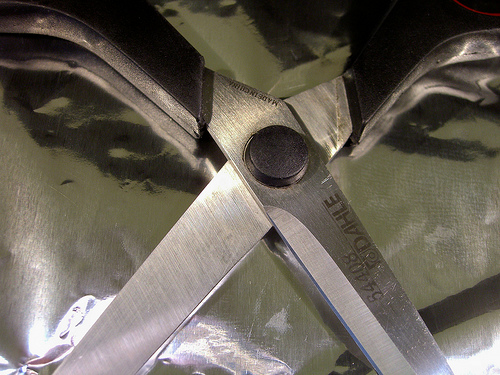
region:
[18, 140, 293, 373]
this is a blade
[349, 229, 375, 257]
this is the letter d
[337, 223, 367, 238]
this is the letter a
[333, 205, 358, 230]
this is the letter h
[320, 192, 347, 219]
this is the letter l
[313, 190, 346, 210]
this is the letter e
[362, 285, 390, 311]
this is the number 3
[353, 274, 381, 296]
this is the number 4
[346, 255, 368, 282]
this is the number 0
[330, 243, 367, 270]
this is the number 8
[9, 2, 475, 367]
scissors on top of tin foil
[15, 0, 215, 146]
black handle of scissors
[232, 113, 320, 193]
black screw to hold scissor blades together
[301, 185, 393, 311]
writing on the silver blade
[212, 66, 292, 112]
made in china writing on the blade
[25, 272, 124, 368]
light shining on tin foil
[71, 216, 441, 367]
two scissor blades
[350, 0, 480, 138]
black plastic handle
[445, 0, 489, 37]
red stripe on black blade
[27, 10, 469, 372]
scissors left open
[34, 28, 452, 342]
this picture is of a tool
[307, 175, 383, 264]
this says "dahle"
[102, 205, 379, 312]
the blades are silver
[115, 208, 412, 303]
these blades are metal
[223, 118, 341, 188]
this connector is black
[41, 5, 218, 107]
the scissor handles are black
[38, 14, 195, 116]
the handle is made of plastic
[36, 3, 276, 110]
this handle is black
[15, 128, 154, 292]
this is aluminum foil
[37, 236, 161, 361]
the foil is very shiny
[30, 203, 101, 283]
These are scissors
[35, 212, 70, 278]
This is tin foil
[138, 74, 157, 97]
This is a handle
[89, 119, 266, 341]
This is made of metal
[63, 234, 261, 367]
The color is silver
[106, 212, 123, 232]
This is made of aluminum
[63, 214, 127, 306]
The tin foil is shiny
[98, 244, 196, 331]
There are no people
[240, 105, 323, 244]
This is a black dot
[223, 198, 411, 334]
The shears are open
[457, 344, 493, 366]
light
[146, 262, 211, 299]
blade of the scissors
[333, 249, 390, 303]
numbers on the scissors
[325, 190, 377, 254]
brand of the scissors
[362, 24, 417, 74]
the handle is black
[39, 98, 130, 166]
reflection of the scissors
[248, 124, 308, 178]
a black bolt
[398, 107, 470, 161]
a reflection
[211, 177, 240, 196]
light on the scissors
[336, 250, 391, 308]
numbers